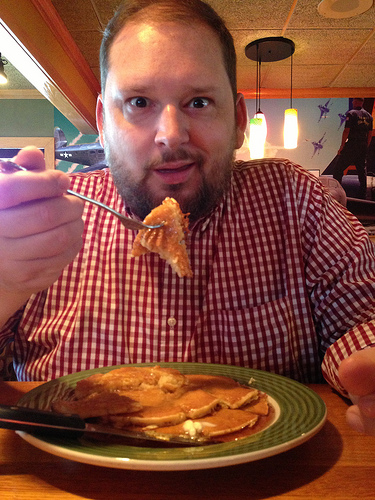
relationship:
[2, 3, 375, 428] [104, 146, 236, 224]
guy has beard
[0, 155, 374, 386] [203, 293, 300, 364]
shirt has pocket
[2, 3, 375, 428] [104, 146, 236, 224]
guy has a beard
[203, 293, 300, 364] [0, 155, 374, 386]
pocket of shirt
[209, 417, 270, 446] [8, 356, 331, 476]
syrup across plate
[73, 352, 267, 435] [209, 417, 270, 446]
pancakes with syrup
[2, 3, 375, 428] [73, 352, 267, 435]
guy eating pancakes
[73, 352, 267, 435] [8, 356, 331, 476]
pancakes on top of plate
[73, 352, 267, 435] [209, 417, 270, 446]
pancakes covered in syrup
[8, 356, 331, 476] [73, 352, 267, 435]
plate of pancakes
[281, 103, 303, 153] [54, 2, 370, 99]
light hang from ceiling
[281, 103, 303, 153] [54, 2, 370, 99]
light hanging from ceiling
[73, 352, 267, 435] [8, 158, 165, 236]
pancakes on end of fork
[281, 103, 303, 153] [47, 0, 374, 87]
light hanging from ceiling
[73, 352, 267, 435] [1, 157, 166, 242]
pancakes on fork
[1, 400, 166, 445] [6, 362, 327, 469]
knife on plate